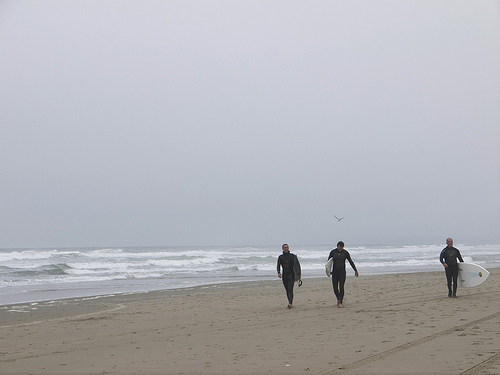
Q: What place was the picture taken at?
A: It was taken at the shore.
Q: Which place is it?
A: It is a shore.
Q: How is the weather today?
A: It is overcast.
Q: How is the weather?
A: It is overcast.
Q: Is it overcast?
A: Yes, it is overcast.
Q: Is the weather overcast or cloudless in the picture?
A: It is overcast.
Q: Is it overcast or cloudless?
A: It is overcast.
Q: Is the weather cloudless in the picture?
A: No, it is overcast.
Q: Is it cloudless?
A: No, it is overcast.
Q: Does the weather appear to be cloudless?
A: No, it is overcast.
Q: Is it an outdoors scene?
A: Yes, it is outdoors.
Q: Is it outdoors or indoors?
A: It is outdoors.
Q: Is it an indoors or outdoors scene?
A: It is outdoors.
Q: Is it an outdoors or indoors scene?
A: It is outdoors.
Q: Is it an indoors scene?
A: No, it is outdoors.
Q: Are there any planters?
A: No, there are no planters.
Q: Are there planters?
A: No, there are no planters.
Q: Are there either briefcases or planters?
A: No, there are no planters or briefcases.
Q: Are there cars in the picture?
A: No, there are no cars.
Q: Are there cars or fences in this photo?
A: No, there are no cars or fences.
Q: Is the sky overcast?
A: Yes, the sky is overcast.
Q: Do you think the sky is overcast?
A: Yes, the sky is overcast.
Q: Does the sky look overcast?
A: Yes, the sky is overcast.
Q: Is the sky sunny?
A: No, the sky is overcast.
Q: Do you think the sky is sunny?
A: No, the sky is overcast.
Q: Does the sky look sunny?
A: No, the sky is overcast.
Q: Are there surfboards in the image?
A: Yes, there is a surfboard.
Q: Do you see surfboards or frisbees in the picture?
A: Yes, there is a surfboard.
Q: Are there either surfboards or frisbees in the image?
A: Yes, there is a surfboard.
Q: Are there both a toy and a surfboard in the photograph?
A: No, there is a surfboard but no toys.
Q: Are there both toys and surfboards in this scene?
A: No, there is a surfboard but no toys.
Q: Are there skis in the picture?
A: No, there are no skis.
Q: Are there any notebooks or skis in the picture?
A: No, there are no skis or notebooks.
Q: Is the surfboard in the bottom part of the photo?
A: Yes, the surfboard is in the bottom of the image.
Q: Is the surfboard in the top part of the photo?
A: No, the surfboard is in the bottom of the image.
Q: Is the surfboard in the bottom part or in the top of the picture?
A: The surfboard is in the bottom of the image.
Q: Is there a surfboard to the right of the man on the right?
A: Yes, there is a surfboard to the right of the man.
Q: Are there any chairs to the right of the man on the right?
A: No, there is a surfboard to the right of the man.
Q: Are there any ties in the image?
A: No, there are no ties.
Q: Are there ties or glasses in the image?
A: No, there are no ties or glasses.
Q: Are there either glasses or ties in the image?
A: No, there are no ties or glasses.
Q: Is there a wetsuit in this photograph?
A: Yes, there is a wetsuit.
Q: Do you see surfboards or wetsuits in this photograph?
A: Yes, there is a wetsuit.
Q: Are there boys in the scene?
A: No, there are no boys.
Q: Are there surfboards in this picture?
A: Yes, there is a surfboard.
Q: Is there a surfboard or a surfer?
A: Yes, there is a surfboard.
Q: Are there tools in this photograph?
A: No, there are no tools.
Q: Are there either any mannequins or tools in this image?
A: No, there are no tools or mannequins.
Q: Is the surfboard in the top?
A: No, the surfboard is in the bottom of the image.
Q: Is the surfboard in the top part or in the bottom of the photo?
A: The surfboard is in the bottom of the image.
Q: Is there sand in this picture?
A: Yes, there is sand.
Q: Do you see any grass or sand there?
A: Yes, there is sand.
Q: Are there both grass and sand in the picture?
A: No, there is sand but no grass.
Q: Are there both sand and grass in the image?
A: No, there is sand but no grass.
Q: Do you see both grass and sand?
A: No, there is sand but no grass.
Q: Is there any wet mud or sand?
A: Yes, there is wet sand.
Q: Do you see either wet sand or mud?
A: Yes, there is wet sand.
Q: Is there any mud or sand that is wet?
A: Yes, the sand is wet.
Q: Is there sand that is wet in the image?
A: Yes, there is wet sand.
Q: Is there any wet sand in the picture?
A: Yes, there is wet sand.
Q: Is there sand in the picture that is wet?
A: Yes, there is sand that is wet.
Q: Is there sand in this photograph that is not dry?
A: Yes, there is wet sand.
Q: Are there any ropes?
A: No, there are no ropes.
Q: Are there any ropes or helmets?
A: No, there are no ropes or helmets.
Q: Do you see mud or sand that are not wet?
A: No, there is sand but it is wet.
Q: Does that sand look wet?
A: Yes, the sand is wet.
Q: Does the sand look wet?
A: Yes, the sand is wet.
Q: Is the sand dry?
A: No, the sand is wet.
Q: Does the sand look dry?
A: No, the sand is wet.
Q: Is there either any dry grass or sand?
A: No, there is sand but it is wet.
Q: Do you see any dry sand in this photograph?
A: No, there is sand but it is wet.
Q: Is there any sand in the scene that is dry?
A: No, there is sand but it is wet.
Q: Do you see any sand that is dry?
A: No, there is sand but it is wet.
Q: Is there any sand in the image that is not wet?
A: No, there is sand but it is wet.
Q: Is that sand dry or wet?
A: The sand is wet.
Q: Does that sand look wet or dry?
A: The sand is wet.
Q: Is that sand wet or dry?
A: The sand is wet.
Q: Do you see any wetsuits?
A: Yes, there is a wetsuit.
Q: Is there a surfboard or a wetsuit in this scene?
A: Yes, there is a wetsuit.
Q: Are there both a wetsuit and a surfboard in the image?
A: Yes, there are both a wetsuit and a surfboard.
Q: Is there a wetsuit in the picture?
A: Yes, there is a wetsuit.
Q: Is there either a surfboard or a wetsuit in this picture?
A: Yes, there is a wetsuit.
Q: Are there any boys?
A: No, there are no boys.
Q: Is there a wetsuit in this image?
A: Yes, there is a wetsuit.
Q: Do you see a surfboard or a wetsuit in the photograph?
A: Yes, there is a wetsuit.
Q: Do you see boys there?
A: No, there are no boys.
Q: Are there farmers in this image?
A: No, there are no farmers.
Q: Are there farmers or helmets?
A: No, there are no farmers or helmets.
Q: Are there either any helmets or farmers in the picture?
A: No, there are no farmers or helmets.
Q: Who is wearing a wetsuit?
A: The man is wearing a wetsuit.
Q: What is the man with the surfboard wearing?
A: The man is wearing a wetsuit.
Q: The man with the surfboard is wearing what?
A: The man is wearing a wetsuit.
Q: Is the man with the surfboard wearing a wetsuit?
A: Yes, the man is wearing a wetsuit.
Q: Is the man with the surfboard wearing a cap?
A: No, the man is wearing a wetsuit.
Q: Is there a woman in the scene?
A: No, there are no women.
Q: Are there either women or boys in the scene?
A: No, there are no women or boys.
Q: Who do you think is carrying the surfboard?
A: The man is carrying the surfboard.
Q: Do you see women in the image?
A: No, there are no women.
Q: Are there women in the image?
A: No, there are no women.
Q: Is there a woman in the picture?
A: No, there are no women.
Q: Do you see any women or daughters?
A: No, there are no women or daughters.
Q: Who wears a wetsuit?
A: The man wears a wetsuit.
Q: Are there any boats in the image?
A: No, there are no boats.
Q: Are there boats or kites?
A: No, there are no boats or kites.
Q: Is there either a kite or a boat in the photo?
A: No, there are no boats or kites.